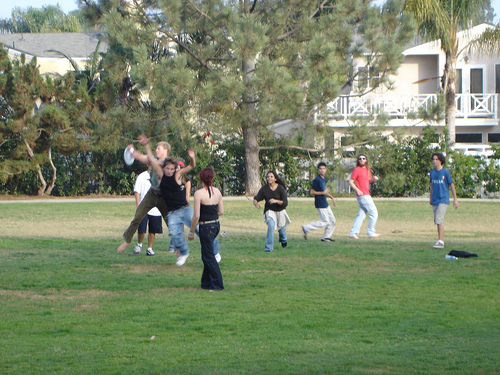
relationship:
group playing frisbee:
[118, 126, 489, 277] [118, 140, 140, 170]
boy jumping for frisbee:
[114, 145, 196, 266] [115, 129, 137, 166]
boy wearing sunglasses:
[345, 148, 385, 240] [356, 156, 366, 162]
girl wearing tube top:
[187, 167, 224, 292] [200, 201, 221, 223]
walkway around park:
[0, 195, 497, 203] [1, 199, 497, 373]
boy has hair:
[348, 154, 378, 239] [356, 152, 367, 170]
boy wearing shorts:
[425, 154, 461, 247] [427, 200, 449, 225]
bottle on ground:
[438, 252, 461, 263] [10, 197, 486, 312]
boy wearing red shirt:
[348, 154, 378, 239] [356, 162, 378, 187]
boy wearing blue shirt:
[430, 153, 458, 248] [428, 165, 453, 205]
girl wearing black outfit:
[187, 167, 224, 292] [197, 200, 222, 290]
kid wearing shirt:
[253, 171, 289, 252] [253, 182, 292, 210]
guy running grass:
[303, 162, 337, 242] [5, 221, 498, 368]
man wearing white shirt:
[133, 160, 162, 255] [135, 168, 170, 215]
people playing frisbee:
[97, 132, 462, 303] [117, 135, 137, 172]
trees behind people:
[3, 5, 498, 196] [114, 124, 466, 299]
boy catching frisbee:
[118, 141, 181, 258] [121, 142, 134, 168]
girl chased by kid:
[187, 166, 227, 292] [252, 162, 295, 248]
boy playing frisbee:
[118, 141, 181, 258] [117, 141, 139, 171]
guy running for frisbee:
[306, 155, 344, 248] [111, 139, 141, 167]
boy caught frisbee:
[119, 122, 186, 249] [118, 138, 146, 168]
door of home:
[452, 63, 485, 113] [308, 17, 498, 198]